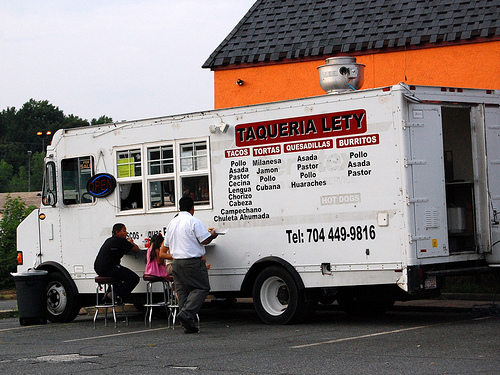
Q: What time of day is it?
A: Afternoon.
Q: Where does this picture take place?
A: On a parking lot.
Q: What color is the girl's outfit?
A: Pink.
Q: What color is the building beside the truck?
A: Orange.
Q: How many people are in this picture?
A: Three.